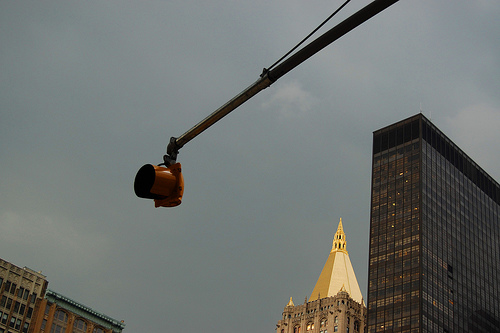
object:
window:
[56, 311, 68, 322]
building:
[0, 259, 128, 333]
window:
[4, 297, 15, 312]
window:
[29, 291, 39, 306]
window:
[22, 288, 32, 301]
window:
[17, 284, 25, 299]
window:
[9, 282, 18, 296]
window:
[2, 279, 12, 294]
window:
[13, 300, 21, 315]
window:
[18, 302, 29, 316]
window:
[26, 307, 35, 320]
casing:
[133, 163, 186, 209]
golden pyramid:
[305, 216, 366, 303]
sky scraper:
[273, 216, 366, 331]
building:
[367, 113, 500, 332]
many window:
[373, 208, 500, 304]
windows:
[367, 222, 419, 247]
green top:
[46, 288, 127, 331]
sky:
[1, 1, 500, 111]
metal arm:
[162, 2, 399, 165]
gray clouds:
[2, 146, 120, 256]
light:
[132, 161, 186, 208]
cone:
[133, 162, 186, 208]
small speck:
[447, 286, 457, 297]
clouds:
[272, 1, 498, 113]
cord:
[258, 0, 350, 72]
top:
[372, 111, 500, 185]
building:
[276, 288, 366, 332]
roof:
[2, 254, 52, 285]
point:
[336, 214, 345, 223]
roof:
[329, 214, 349, 251]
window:
[333, 315, 341, 324]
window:
[352, 319, 361, 330]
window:
[285, 312, 294, 320]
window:
[333, 324, 341, 332]